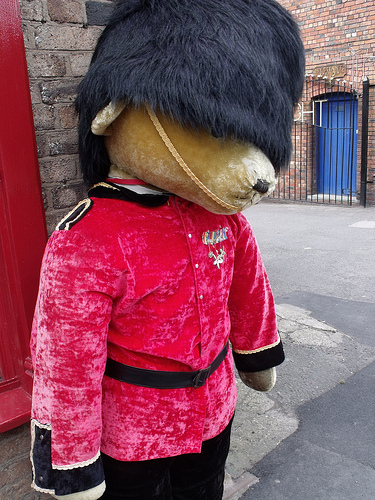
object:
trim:
[231, 330, 281, 353]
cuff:
[231, 335, 285, 374]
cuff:
[28, 454, 106, 499]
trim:
[49, 444, 101, 471]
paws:
[237, 349, 283, 396]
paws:
[31, 458, 108, 498]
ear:
[86, 98, 132, 137]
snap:
[32, 427, 51, 443]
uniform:
[28, 173, 286, 500]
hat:
[75, 0, 306, 186]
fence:
[264, 82, 373, 204]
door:
[304, 88, 367, 203]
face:
[109, 96, 278, 218]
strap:
[135, 95, 252, 218]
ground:
[309, 90, 354, 201]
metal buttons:
[184, 223, 205, 313]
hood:
[72, 0, 306, 188]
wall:
[245, 1, 373, 208]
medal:
[202, 226, 232, 267]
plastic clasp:
[192, 364, 211, 388]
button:
[38, 433, 44, 440]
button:
[38, 472, 45, 482]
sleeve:
[226, 228, 285, 374]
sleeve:
[29, 228, 121, 495]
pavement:
[0, 198, 375, 496]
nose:
[254, 177, 269, 193]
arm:
[229, 225, 284, 391]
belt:
[100, 344, 233, 390]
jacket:
[29, 179, 285, 498]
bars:
[265, 0, 375, 204]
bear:
[28, 0, 308, 499]